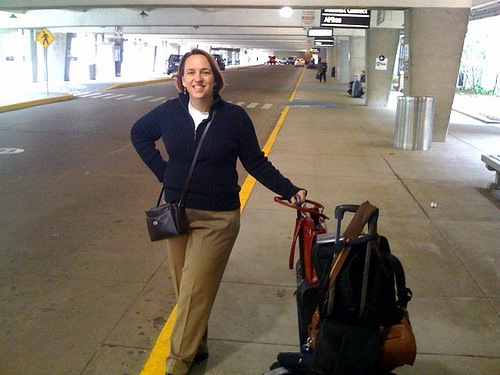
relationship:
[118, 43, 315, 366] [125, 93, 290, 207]
she wearing blue shirt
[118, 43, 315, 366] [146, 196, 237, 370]
she wearing tan pants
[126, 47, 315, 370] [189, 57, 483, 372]
woman standing on sidewalk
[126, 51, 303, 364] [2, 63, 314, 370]
woman standing on road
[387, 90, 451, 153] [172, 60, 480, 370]
dustbin on roadside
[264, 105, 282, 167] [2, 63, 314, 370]
yellow paint on road